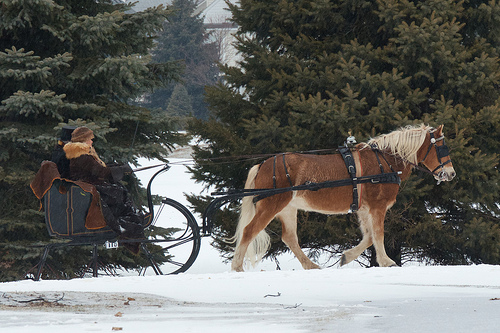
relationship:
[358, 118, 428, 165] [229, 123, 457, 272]
long hair on brown horse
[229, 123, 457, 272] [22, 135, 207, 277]
brown horse on cart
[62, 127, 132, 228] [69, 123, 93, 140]
lady wears cap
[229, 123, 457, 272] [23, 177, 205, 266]
brown horse pulls sled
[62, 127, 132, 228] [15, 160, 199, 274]
lady sitting in sled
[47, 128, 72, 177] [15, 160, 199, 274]
passenger sitting in sled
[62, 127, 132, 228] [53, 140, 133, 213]
lady wearing coat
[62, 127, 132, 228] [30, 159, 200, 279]
lady in sled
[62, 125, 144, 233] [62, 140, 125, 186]
lady wearing coat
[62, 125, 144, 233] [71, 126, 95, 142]
lady wearing cap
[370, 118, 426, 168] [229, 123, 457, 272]
mane on brown horse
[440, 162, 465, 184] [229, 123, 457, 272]
nose on brown horse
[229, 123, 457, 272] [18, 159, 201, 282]
brown horse pulling carriage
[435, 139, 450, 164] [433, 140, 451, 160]
blinder over horse eye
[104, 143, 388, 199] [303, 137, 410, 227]
reigns attached to harness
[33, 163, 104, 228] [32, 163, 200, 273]
fabric inside of carriage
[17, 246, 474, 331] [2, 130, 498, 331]
white snow covering ground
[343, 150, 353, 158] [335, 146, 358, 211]
metal buckles on black harnass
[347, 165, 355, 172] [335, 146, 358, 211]
metal buckles on black harnass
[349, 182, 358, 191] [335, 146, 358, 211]
metal buckles on black harnass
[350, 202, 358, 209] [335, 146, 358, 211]
metal buckles on black harnass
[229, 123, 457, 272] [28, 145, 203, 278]
brown horse in front of sleigh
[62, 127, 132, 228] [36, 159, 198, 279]
lady riding in sleigh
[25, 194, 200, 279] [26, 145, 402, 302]
gliders on sleigh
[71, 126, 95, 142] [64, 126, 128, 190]
cap on rider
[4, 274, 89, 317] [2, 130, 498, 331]
twig on ground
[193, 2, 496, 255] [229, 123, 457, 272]
tree near brown horse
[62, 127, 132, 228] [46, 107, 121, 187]
lady wearing coat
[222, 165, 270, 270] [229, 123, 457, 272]
tail belonging to brown horse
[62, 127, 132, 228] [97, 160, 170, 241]
lady holding rope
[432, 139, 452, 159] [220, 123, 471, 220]
blinder on horse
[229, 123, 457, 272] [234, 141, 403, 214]
brown horse wearing harness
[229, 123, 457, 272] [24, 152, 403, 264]
brown horse pulling sleigh